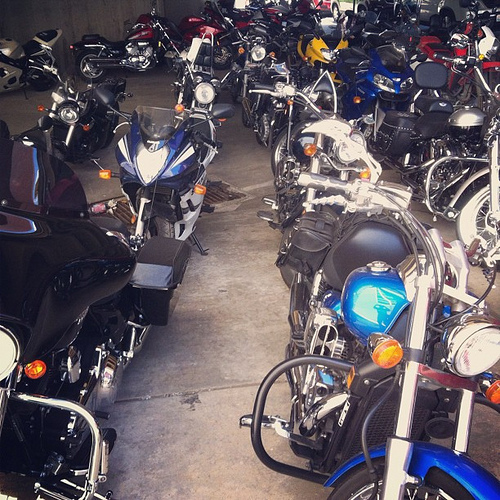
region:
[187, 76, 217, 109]
light on a motorcycle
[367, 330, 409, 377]
light on a motorcycle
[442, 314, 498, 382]
light on a motorcycle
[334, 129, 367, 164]
light on a motorcycle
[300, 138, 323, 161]
light on a motorcycle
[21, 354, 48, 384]
light on a motorcycle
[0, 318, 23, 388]
light on a motorcycle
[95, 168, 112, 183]
light on a motorcycle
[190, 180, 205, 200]
light on a motorcycle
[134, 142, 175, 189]
light on a motorcycle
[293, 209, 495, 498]
blue motorcycle in front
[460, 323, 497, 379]
headlight on the motorcycle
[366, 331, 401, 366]
right turn signal on motorcycle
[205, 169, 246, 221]
drain in the floor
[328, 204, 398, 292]
leather seat on motorcycle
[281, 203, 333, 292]
right side saddlebag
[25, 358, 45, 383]
left turn signal on black cycle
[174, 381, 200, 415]
dirt on cement floor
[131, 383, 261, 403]
crack in the cement floor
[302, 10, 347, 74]
yellow motorcycle in back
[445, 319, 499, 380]
Headlight of motorcycle.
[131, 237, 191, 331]
Side storage box of motorcycle.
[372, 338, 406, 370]
Yellow turn signal on motorcycle.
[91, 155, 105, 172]
motorcycle kick stand.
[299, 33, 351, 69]
Yellow front to motorcycle.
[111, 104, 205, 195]
Royal blue front with bug shield.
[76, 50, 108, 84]
Rear tire on motorcycle.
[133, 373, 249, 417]
Seam in concrete floor.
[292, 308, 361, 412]
Side engine of motorcycle.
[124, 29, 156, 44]
Red front compartment of motorcycle.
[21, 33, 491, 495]
a whole lot of motorcycles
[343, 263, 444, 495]
this one is blue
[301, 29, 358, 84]
this one is yellow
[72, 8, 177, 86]
this one has a red gas tank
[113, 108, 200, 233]
this one is blue with white stripes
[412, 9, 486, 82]
this one is red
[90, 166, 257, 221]
a grate is in the center of the photo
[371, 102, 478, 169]
this bike has saddle bags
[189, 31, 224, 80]
this bike has a "sissy" bar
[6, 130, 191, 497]
this bike is full dress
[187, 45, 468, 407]
Motorcycles parked on street.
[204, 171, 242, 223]
Drainer on the ground.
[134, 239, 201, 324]
Black box on motorcycle.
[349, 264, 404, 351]
The motorcycle is blue.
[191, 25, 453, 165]
Motorcycles next to each other.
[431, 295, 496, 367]
Headlight on motorcycle.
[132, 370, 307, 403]
A crack on the ground.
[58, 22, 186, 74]
A red motorcycle is by the wall.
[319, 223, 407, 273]
The seat is black.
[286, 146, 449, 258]
Handle on the motorcycle.